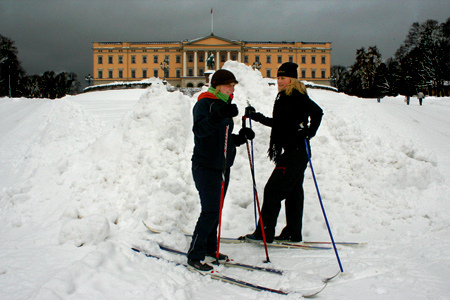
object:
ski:
[131, 227, 302, 297]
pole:
[216, 121, 231, 267]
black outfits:
[191, 94, 255, 166]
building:
[90, 7, 334, 94]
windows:
[321, 69, 326, 78]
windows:
[311, 69, 316, 78]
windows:
[321, 56, 326, 63]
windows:
[301, 55, 306, 63]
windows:
[266, 55, 271, 63]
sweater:
[255, 89, 324, 161]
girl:
[186, 69, 254, 272]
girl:
[244, 62, 326, 242]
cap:
[211, 69, 238, 88]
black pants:
[254, 160, 307, 242]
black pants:
[185, 162, 230, 258]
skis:
[130, 239, 369, 299]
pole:
[304, 140, 346, 274]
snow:
[1, 59, 449, 297]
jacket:
[252, 89, 324, 161]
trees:
[330, 16, 449, 103]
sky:
[6, 6, 449, 62]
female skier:
[243, 62, 324, 245]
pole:
[240, 116, 273, 264]